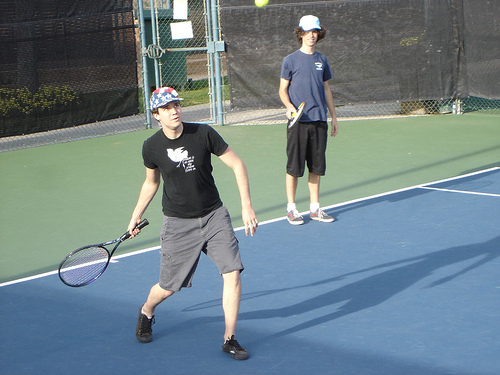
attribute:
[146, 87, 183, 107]
cap — red, white, blue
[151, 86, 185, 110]
hat — American flag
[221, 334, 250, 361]
sneakers — black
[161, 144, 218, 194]
print — white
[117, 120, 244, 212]
shirt — black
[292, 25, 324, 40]
hair — curly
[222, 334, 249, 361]
shoe — black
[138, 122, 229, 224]
tshirt — black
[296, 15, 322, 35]
baseball cap — white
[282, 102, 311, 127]
racquet — tennis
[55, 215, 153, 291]
racket — tennis, black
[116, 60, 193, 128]
hat — white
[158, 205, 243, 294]
shorts — gray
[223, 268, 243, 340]
leg — bare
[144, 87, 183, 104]
flag hat — american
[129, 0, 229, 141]
fence — chain link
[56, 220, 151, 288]
tennis racket — black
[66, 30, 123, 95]
fence — chain link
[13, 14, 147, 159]
cover — black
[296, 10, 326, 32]
cap — white, ball cap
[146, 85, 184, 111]
ball cap — flag themed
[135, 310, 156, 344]
shoe — black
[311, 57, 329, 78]
print — white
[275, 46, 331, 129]
shirt — blue